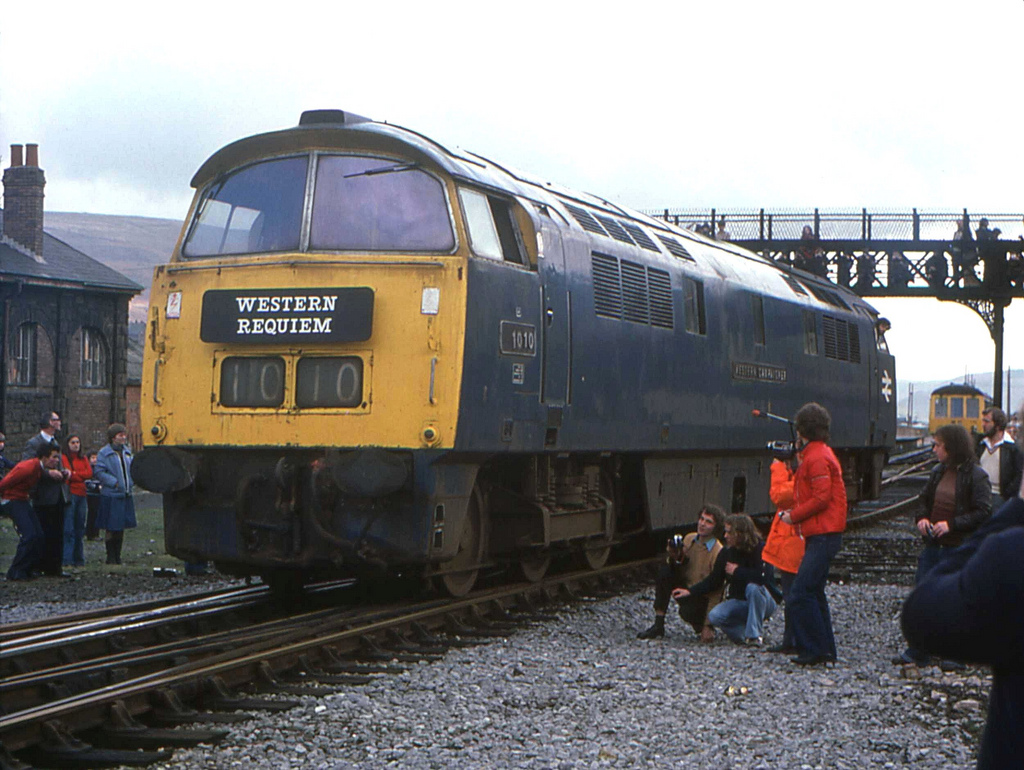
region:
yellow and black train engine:
[143, 115, 897, 593]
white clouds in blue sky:
[639, 92, 688, 125]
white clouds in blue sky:
[61, 80, 134, 144]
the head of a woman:
[763, 399, 830, 445]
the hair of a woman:
[813, 411, 827, 437]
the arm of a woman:
[778, 473, 851, 516]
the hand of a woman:
[781, 505, 789, 528]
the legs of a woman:
[763, 525, 841, 665]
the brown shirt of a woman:
[912, 464, 988, 528]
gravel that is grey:
[444, 660, 666, 765]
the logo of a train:
[198, 274, 382, 367]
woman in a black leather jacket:
[908, 420, 995, 545]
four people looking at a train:
[4, 402, 140, 579]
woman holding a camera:
[906, 420, 989, 545]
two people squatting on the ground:
[629, 500, 775, 652]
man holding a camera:
[636, 500, 725, 643]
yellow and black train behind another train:
[915, 375, 988, 429]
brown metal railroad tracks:
[1, 597, 493, 759]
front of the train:
[78, 114, 519, 598]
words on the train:
[205, 255, 399, 370]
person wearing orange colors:
[704, 345, 907, 612]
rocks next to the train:
[432, 600, 647, 756]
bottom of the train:
[297, 414, 740, 618]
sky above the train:
[578, 56, 860, 148]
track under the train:
[73, 566, 369, 734]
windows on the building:
[0, 276, 163, 401]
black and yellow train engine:
[140, 89, 924, 451]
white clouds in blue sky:
[84, 13, 189, 86]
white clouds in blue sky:
[889, 92, 962, 132]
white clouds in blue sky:
[725, 37, 809, 115]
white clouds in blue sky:
[532, 43, 622, 119]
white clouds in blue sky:
[368, 22, 485, 95]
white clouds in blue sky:
[131, 75, 186, 118]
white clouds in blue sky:
[93, 63, 154, 103]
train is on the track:
[125, 105, 898, 597]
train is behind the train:
[931, 385, 992, 450]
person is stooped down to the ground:
[669, 512, 774, 648]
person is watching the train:
[89, 421, 138, 568]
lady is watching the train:
[888, 423, 988, 671]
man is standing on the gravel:
[973, 402, 1022, 502]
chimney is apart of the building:
[3, 145, 48, 262]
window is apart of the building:
[68, 326, 114, 388]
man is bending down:
[3, 439, 61, 583]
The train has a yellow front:
[144, 88, 644, 699]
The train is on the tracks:
[89, 69, 662, 756]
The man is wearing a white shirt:
[958, 382, 1019, 526]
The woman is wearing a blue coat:
[76, 397, 160, 560]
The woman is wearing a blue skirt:
[87, 418, 160, 532]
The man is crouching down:
[639, 484, 732, 634]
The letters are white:
[248, 293, 353, 338]